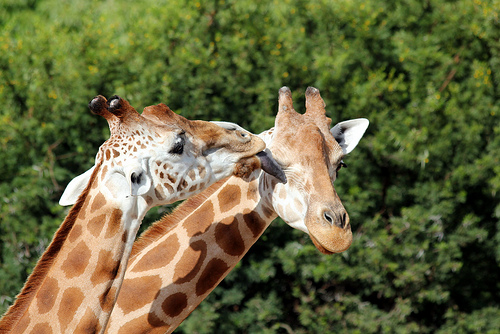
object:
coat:
[0, 201, 123, 334]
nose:
[216, 120, 255, 143]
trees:
[0, 0, 499, 334]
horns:
[101, 93, 136, 125]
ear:
[121, 160, 157, 199]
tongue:
[259, 149, 290, 186]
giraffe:
[0, 79, 294, 334]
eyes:
[163, 131, 195, 160]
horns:
[273, 81, 300, 119]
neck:
[98, 183, 265, 334]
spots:
[205, 211, 250, 259]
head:
[66, 91, 292, 218]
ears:
[51, 164, 101, 211]